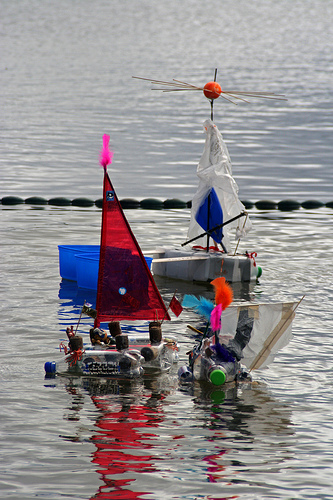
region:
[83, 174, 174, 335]
A boat with a red sail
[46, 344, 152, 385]
A bottle floating in the water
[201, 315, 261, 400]
A bottle made like a boat.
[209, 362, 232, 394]
The top of the bottle is green.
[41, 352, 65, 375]
The bottle cap is blue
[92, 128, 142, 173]
A pink feather on top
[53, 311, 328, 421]
Bottles made boats floating in the water.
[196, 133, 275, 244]
The sail is white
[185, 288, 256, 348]
The feathers are colorful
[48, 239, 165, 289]
blue tubs floating in the water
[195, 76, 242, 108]
Orange sphere on a handmade boat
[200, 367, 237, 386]
Green bottle cap on handmade boat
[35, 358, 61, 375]
Blue bottle cap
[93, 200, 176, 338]
Red sail on hand made boat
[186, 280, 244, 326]
Pink, orange and blue feathers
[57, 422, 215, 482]
Water three boats are floating in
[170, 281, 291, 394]
Hand made boat floating in the water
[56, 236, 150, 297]
Two blue boxes floating in the water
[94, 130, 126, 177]
Pink feather on a red sail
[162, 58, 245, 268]
Handmade boat with a clear sail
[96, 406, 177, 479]
the reflection is red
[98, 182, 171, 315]
the piece of material is red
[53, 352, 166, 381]
empty bottle floating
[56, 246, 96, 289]
the containers are blue in color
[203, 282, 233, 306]
it is orange in color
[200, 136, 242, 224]
the material is white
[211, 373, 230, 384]
the bottletop is green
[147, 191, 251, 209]
the floating material is black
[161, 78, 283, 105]
sticks attache to orange ball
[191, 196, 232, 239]
blue clothing on sticks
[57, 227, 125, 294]
Two blue box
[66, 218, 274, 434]
waste bottle are made into boat.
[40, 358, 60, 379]
cap is blue in color.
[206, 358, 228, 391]
cap is green in color.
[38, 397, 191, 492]
water is blue in color.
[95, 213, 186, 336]
flag is red color.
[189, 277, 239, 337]
feathers are orange, blue and pink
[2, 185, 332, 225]
chain is seen in water.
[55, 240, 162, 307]
boxes are floating in the water.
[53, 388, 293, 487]
reflection is seen in water.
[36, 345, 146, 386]
an empty soda bottle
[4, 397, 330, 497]
a lake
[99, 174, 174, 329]
a boat sail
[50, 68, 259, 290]
a homemade toy boat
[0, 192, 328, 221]
a fence to block off the toy boats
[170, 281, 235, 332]
three colorful feathers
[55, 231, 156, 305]
two blue buckets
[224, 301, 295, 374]
a white sail for the boat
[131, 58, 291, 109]
a toy umbrella for the boat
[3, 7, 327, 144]
water of the lake